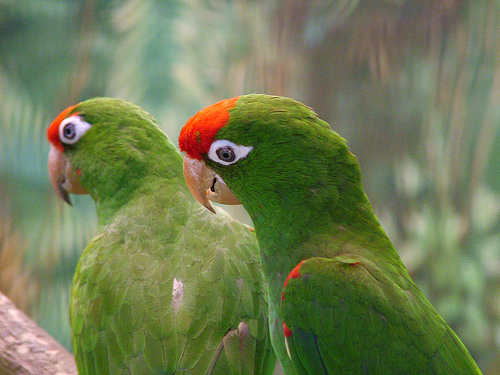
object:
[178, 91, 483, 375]
bird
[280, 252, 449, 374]
wing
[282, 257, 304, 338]
red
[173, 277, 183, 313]
white spot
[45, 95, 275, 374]
bird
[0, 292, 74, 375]
branch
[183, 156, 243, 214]
beak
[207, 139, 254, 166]
white area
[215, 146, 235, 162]
eye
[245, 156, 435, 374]
feathers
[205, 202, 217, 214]
tip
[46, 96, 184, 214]
head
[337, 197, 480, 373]
back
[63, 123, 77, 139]
eye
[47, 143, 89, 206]
beak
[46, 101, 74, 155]
red